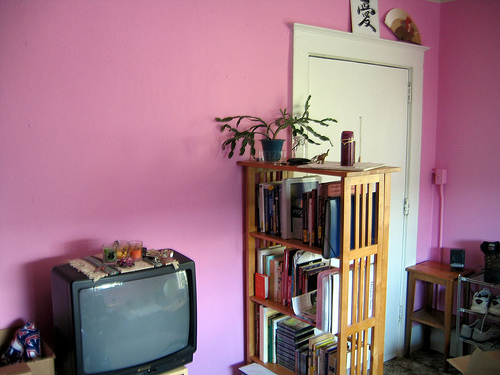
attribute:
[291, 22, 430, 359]
door frame — white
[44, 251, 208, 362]
television — box shaped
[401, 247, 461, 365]
table — small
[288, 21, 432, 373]
door — white, brown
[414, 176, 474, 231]
pipe — pink and metal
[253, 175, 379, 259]
books — collection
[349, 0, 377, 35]
sign — white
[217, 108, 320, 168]
plant — green 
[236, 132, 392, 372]
book case — wooden 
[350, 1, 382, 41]
paper — white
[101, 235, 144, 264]
candles — placed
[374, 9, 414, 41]
fan — above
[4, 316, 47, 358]
piece — blue, art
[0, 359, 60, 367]
box — brown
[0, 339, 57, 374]
box — brown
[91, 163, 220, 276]
wall — pink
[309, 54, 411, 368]
door — white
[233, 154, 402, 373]
bookcase — wooden, light brown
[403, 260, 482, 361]
end table — wooden 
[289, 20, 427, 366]
frame — white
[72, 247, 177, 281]
cloth — white